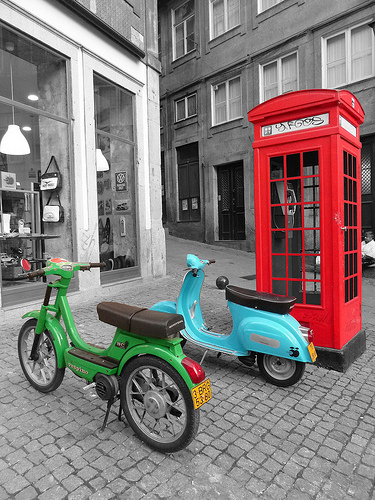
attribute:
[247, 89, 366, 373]
phone booth — red, old fashioned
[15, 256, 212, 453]
scooter — parked, green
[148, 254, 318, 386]
scooter — blue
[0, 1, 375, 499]
background — black, white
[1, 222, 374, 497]
sidewalk — gray, grey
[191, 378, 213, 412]
license plate — yellow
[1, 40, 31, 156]
light — hanging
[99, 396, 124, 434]
kickstand — black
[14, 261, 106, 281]
handles — black